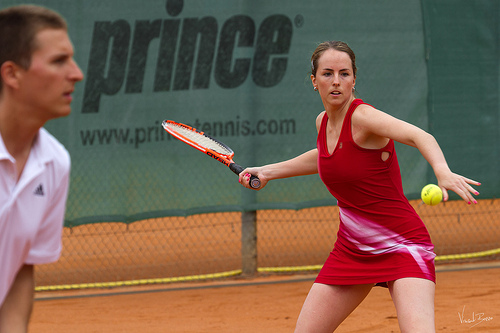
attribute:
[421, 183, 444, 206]
ball — yellow, flying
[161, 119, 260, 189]
racket — red, orange, colored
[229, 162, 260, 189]
grip — black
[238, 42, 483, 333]
player — preparing, playing, here, swinging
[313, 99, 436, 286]
dress — colored, short, red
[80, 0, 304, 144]
ad — black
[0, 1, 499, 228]
fence — green, chain, metal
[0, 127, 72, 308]
shirt — white, pink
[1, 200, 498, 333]
court — clayed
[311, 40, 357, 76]
hair — brown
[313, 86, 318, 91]
earrings — silver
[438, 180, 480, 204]
nails — short, pink, red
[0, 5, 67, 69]
hair — short, brown